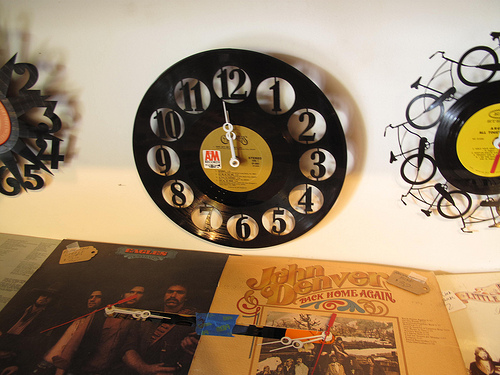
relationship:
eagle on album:
[60, 287, 194, 347] [22, 216, 239, 372]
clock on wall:
[121, 36, 382, 273] [56, 14, 412, 306]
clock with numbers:
[121, 36, 382, 273] [225, 182, 320, 241]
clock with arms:
[121, 36, 382, 273] [203, 88, 268, 194]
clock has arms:
[121, 36, 382, 273] [221, 102, 241, 168]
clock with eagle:
[121, 36, 382, 273] [60, 287, 194, 347]